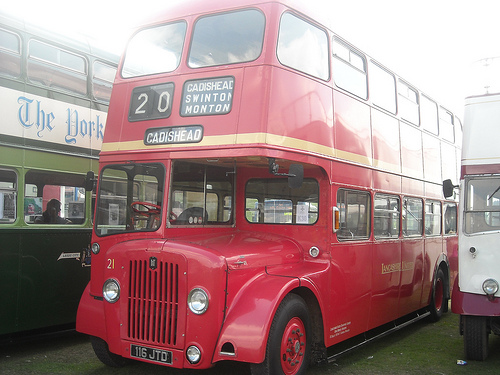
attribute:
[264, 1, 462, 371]
bus — SIDE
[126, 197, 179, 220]
wheel — STEERING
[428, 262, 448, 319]
wheel — BACK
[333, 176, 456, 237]
windows — SIDE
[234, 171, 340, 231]
window — small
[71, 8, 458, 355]
bus — red, red and yellow, double decker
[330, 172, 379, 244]
window — small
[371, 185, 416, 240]
window — small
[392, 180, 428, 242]
window — small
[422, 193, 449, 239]
window — small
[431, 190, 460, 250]
window — small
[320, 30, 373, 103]
window — small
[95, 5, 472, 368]
bus — decker, red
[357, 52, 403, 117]
window — small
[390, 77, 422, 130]
window — small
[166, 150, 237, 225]
window — small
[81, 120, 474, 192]
trim — gold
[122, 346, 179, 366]
plate — black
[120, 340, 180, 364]
letters — white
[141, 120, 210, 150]
sign — black, destination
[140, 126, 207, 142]
letters — white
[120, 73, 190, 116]
sign — bus, black, number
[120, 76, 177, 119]
numerals — white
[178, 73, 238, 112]
sign — black, route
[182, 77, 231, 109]
letters — white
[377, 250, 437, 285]
lettering — gold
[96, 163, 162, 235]
window — driver's front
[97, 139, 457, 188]
trim — gold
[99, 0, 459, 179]
level — upper level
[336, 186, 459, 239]
windows — side windows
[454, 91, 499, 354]
bus — white and red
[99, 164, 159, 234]
window — driver's window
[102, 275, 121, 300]
headlight — driver's side headlight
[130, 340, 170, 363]
license plate — black and silver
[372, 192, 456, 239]
windows — passenger windows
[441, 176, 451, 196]
mirror — rear view mirror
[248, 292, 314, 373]
tire — black, front tire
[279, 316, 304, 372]
rim — red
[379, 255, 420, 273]
writing — gold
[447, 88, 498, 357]
bus — white